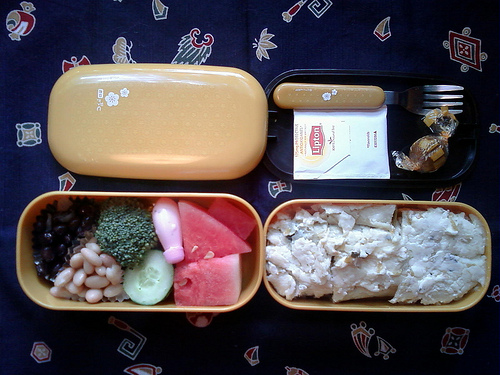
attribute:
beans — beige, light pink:
[49, 245, 124, 301]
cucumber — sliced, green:
[125, 249, 172, 305]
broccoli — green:
[97, 202, 158, 267]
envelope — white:
[295, 106, 391, 180]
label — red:
[310, 123, 328, 156]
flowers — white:
[105, 85, 134, 110]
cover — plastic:
[46, 64, 269, 181]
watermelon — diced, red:
[174, 202, 251, 306]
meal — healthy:
[32, 200, 251, 306]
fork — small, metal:
[272, 84, 465, 114]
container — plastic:
[16, 190, 263, 313]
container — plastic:
[262, 200, 492, 312]